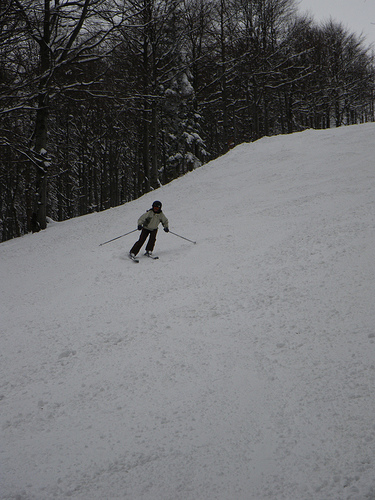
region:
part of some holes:
[171, 428, 221, 466]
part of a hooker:
[180, 233, 206, 246]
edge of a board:
[132, 255, 143, 261]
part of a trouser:
[141, 214, 157, 262]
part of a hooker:
[105, 233, 118, 247]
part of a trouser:
[144, 233, 151, 240]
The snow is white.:
[92, 351, 261, 456]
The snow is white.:
[125, 310, 346, 455]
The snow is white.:
[32, 306, 215, 413]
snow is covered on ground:
[175, 176, 367, 496]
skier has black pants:
[124, 227, 157, 242]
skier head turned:
[147, 199, 164, 209]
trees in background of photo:
[66, 85, 144, 198]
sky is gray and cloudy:
[295, 0, 350, 18]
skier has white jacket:
[137, 210, 159, 229]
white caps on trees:
[187, 131, 234, 158]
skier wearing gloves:
[154, 225, 172, 236]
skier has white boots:
[127, 255, 136, 263]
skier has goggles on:
[148, 201, 166, 210]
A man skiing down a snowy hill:
[94, 196, 199, 264]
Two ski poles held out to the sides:
[95, 221, 200, 246]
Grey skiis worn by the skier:
[126, 246, 161, 263]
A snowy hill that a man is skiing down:
[1, 119, 373, 498]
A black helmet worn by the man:
[149, 198, 163, 212]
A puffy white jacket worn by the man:
[133, 207, 172, 232]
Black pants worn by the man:
[127, 225, 158, 253]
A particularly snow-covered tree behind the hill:
[155, 45, 212, 173]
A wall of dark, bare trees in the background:
[0, 0, 374, 243]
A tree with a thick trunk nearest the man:
[9, 0, 104, 236]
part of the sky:
[345, 0, 361, 7]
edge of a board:
[129, 246, 146, 263]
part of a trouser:
[128, 189, 145, 255]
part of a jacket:
[151, 217, 166, 229]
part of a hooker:
[174, 228, 197, 248]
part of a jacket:
[152, 222, 164, 230]